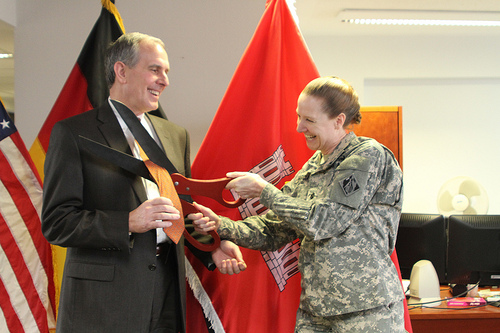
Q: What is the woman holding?
A: Giant scissors.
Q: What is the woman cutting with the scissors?
A: Tie.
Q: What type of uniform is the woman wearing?
A: Military.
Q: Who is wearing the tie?
A: The man.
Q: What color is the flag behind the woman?
A: Red.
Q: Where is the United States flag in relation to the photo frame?
A: Left.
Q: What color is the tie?
A: Orange.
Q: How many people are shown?
A: Two.